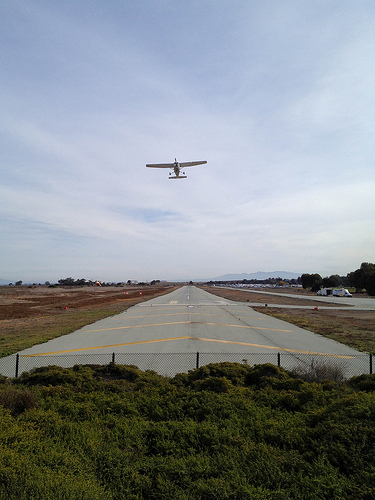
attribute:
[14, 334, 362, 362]
line — yellow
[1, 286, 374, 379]
runway — paved, gray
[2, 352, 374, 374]
fence — metal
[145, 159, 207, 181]
airplane — white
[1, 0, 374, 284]
sky — cloudy, blue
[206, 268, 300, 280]
hill — distant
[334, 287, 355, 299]
truck — white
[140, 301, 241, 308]
line — white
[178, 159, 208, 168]
wing — white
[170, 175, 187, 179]
tail — white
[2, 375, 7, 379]
leaf — green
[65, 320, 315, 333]
paint — yellow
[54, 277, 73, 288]
tree — distant, green